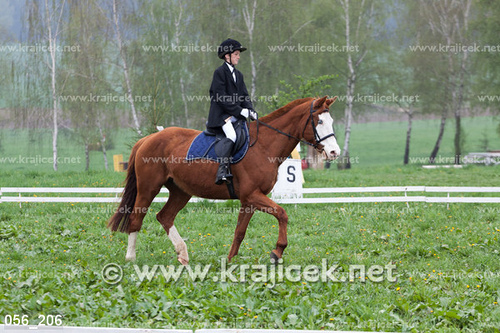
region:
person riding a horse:
[94, 33, 346, 272]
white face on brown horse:
[318, 111, 337, 160]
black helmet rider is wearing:
[218, 39, 239, 56]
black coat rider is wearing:
[208, 64, 249, 128]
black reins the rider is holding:
[241, 97, 288, 140]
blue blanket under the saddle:
[191, 123, 243, 166]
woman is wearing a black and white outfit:
[190, 33, 274, 185]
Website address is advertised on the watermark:
[93, 249, 405, 299]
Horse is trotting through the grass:
[95, 89, 350, 270]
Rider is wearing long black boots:
[209, 130, 250, 187]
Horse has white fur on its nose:
[297, 85, 356, 173]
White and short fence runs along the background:
[6, 181, 497, 230]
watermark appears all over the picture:
[7, 7, 499, 332]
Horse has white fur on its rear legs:
[104, 191, 205, 278]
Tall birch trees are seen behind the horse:
[26, 12, 486, 202]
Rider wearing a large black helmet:
[213, 33, 250, 72]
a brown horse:
[108, 86, 342, 271]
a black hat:
[211, 30, 245, 61]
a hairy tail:
[100, 130, 147, 233]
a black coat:
[206, 60, 248, 132]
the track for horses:
[0, 183, 499, 198]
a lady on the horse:
[201, 34, 258, 188]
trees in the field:
[1, 2, 496, 174]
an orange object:
[111, 145, 126, 176]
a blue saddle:
[185, 113, 254, 164]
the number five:
[281, 163, 299, 187]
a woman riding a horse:
[202, 35, 258, 183]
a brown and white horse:
[105, 91, 337, 266]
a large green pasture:
[0, 111, 495, 327]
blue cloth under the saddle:
[185, 122, 246, 158]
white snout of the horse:
[315, 110, 340, 157]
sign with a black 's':
[275, 155, 296, 185]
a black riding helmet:
[218, 39, 246, 59]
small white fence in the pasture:
[0, 180, 499, 209]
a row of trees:
[0, 1, 499, 169]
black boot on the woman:
[216, 158, 233, 185]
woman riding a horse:
[110, 28, 365, 259]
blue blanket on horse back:
[180, 121, 246, 172]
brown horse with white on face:
[122, 91, 338, 281]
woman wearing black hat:
[186, 22, 268, 187]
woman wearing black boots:
[185, 14, 267, 191]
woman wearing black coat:
[197, 19, 256, 183]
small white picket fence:
[3, 168, 495, 230]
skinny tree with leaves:
[370, 49, 431, 166]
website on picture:
[94, 244, 400, 294]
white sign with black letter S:
[272, 153, 311, 193]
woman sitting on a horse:
[183, 21, 266, 188]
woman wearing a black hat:
[206, 31, 250, 62]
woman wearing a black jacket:
[207, 58, 253, 122]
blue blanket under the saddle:
[174, 118, 248, 158]